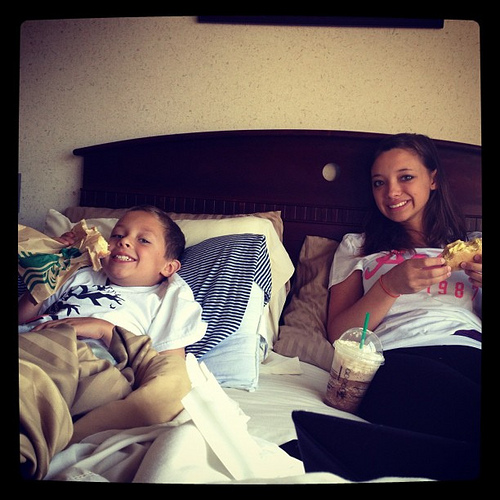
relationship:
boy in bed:
[20, 203, 210, 478] [52, 123, 497, 475]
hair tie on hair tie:
[377, 278, 397, 300] [379, 275, 400, 298]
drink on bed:
[321, 305, 387, 418] [52, 123, 497, 475]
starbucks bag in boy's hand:
[17, 217, 113, 304] [55, 233, 77, 249]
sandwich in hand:
[436, 236, 480, 271] [388, 252, 452, 293]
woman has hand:
[326, 133, 482, 444] [388, 252, 452, 293]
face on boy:
[102, 210, 160, 278] [20, 203, 210, 478]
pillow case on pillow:
[162, 227, 277, 359] [168, 229, 278, 400]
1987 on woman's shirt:
[421, 275, 479, 303] [328, 225, 482, 351]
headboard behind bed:
[70, 128, 481, 323] [52, 123, 497, 475]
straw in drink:
[359, 312, 369, 349] [335, 312, 377, 405]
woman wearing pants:
[300, 120, 497, 478] [289, 330, 484, 481]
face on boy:
[100, 210, 160, 278] [20, 208, 209, 364]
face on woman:
[374, 143, 422, 223] [326, 133, 482, 444]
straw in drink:
[357, 312, 369, 349] [321, 326, 383, 412]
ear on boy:
[160, 254, 180, 281] [20, 203, 210, 478]